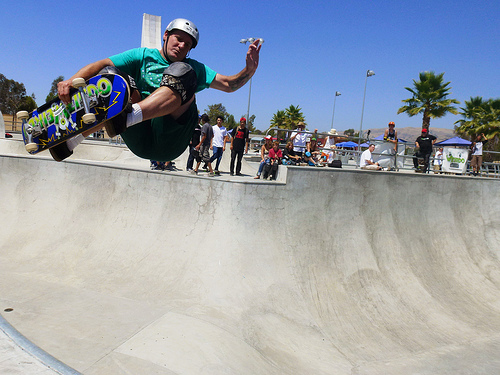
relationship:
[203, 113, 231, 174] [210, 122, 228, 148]
person wearing t-shirt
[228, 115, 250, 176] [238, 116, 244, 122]
man wearing hat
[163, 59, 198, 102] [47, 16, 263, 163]
kneepad on man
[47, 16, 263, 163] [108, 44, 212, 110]
man in shirt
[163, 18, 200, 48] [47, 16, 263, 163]
helmet on man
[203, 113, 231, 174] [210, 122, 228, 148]
person in t-shirt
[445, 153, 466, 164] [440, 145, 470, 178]
text on sign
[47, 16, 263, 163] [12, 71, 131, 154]
man on skateboard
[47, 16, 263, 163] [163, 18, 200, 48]
man wearing helmet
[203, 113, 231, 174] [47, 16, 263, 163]
person watching man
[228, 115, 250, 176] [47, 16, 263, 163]
man watching man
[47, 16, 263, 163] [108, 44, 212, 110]
man wearing shirt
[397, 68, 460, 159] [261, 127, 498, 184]
tree behind fence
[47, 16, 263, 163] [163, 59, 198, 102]
man wearing kneepad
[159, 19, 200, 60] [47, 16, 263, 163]
head of man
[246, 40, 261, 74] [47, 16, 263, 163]
hand of man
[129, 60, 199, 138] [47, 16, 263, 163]
leg of man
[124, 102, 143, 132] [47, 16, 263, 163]
sock on man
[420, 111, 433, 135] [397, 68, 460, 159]
trunk of tree